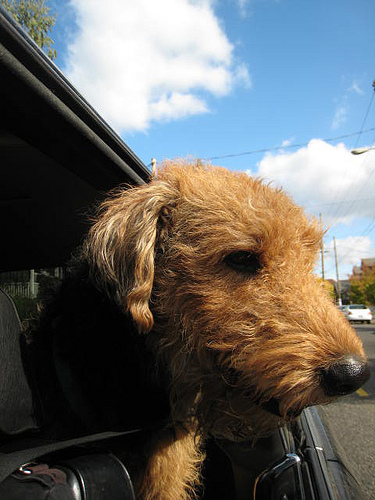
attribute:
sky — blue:
[118, 27, 339, 145]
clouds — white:
[53, 0, 264, 140]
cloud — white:
[60, 3, 251, 142]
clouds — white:
[69, 3, 245, 120]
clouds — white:
[252, 138, 374, 216]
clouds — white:
[315, 233, 373, 271]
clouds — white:
[332, 68, 360, 128]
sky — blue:
[67, 0, 372, 208]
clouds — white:
[92, 27, 217, 105]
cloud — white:
[255, 130, 373, 231]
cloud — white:
[51, 1, 247, 125]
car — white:
[346, 305, 372, 323]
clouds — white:
[58, 0, 249, 133]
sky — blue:
[8, 1, 371, 281]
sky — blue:
[192, 11, 372, 146]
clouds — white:
[214, 8, 245, 66]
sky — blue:
[49, 6, 373, 121]